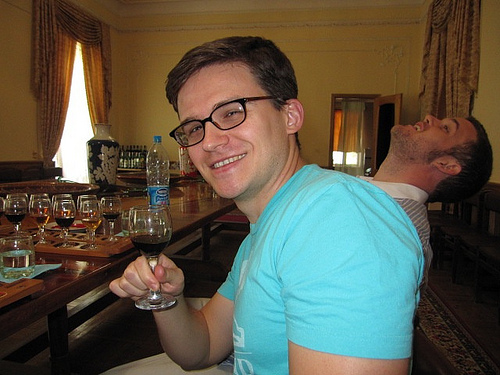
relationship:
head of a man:
[396, 86, 493, 198] [358, 100, 484, 290]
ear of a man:
[429, 153, 465, 178] [141, 52, 468, 340]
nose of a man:
[422, 112, 439, 128] [358, 100, 484, 290]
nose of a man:
[195, 121, 233, 153] [109, 31, 421, 373]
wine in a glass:
[129, 234, 172, 253] [125, 203, 181, 310]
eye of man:
[221, 107, 246, 119] [140, 34, 407, 368]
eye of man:
[188, 125, 208, 133] [140, 34, 407, 368]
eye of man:
[441, 120, 451, 134] [360, 112, 490, 232]